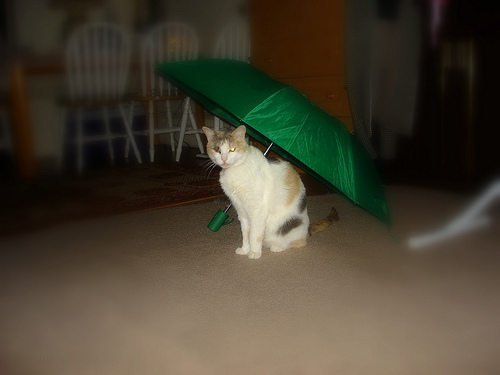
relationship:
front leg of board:
[400, 186, 500, 250] [490, 151, 499, 169]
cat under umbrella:
[192, 115, 345, 257] [152, 44, 397, 228]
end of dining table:
[3, 50, 35, 172] [10, 46, 211, 177]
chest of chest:
[253, 71, 352, 136] [248, 2, 348, 142]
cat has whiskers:
[192, 115, 345, 257] [191, 156, 261, 175]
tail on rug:
[303, 205, 342, 243] [3, 189, 500, 372]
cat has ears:
[192, 115, 345, 257] [195, 126, 253, 139]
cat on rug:
[192, 115, 345, 257] [3, 189, 500, 372]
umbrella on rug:
[152, 44, 397, 228] [3, 189, 500, 372]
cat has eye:
[192, 115, 345, 257] [228, 143, 236, 151]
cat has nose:
[192, 115, 345, 257] [218, 152, 231, 160]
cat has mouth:
[192, 115, 345, 257] [218, 160, 233, 168]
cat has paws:
[192, 115, 345, 257] [228, 241, 289, 259]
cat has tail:
[192, 115, 345, 257] [303, 205, 342, 243]